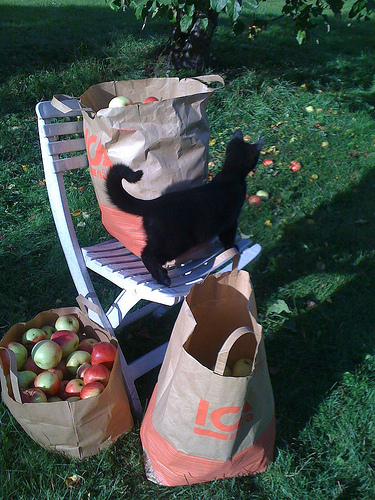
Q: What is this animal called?
A: Cat.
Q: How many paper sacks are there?
A: Three.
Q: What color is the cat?
A: Black.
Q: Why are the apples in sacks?
A: To carry them.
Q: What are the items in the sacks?
A: Apples.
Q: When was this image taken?
A: Daytime.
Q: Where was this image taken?
A: In the backyard.